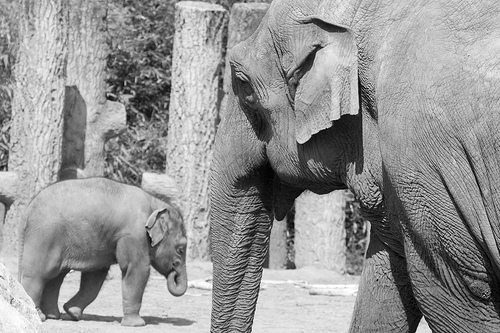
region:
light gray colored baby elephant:
[12, 175, 190, 331]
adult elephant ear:
[276, 12, 366, 148]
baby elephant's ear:
[142, 206, 175, 251]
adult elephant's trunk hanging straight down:
[198, 103, 278, 330]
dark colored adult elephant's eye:
[227, 65, 260, 105]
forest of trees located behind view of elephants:
[2, 0, 382, 277]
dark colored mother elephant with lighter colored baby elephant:
[12, 23, 494, 330]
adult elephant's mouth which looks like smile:
[247, 140, 318, 227]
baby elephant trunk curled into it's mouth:
[159, 260, 198, 301]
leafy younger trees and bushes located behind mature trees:
[1, 0, 364, 273]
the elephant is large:
[206, 4, 498, 331]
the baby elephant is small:
[17, 173, 191, 330]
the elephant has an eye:
[209, 3, 497, 332]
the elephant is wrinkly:
[206, 0, 498, 332]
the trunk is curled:
[161, 273, 193, 296]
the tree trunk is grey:
[4, 5, 218, 175]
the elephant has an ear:
[201, 0, 498, 332]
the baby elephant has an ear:
[16, 179, 193, 327]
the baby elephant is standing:
[12, 176, 195, 313]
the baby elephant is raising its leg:
[22, 175, 194, 321]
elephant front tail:
[192, 192, 289, 329]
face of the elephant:
[166, 13, 356, 245]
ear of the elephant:
[278, 23, 374, 141]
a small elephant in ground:
[21, 165, 209, 321]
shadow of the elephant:
[91, 303, 202, 328]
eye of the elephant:
[221, 55, 281, 113]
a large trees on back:
[8, 0, 273, 330]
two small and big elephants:
[17, 23, 489, 332]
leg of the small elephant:
[106, 273, 158, 329]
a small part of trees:
[104, 0, 179, 131]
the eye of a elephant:
[186, 56, 288, 113]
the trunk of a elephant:
[194, 170, 336, 322]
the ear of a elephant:
[286, 4, 372, 141]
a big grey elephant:
[177, 2, 494, 326]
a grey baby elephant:
[15, 180, 212, 303]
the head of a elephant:
[195, 2, 410, 196]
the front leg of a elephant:
[113, 227, 167, 329]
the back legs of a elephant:
[25, 213, 72, 325]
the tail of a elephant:
[11, 209, 45, 270]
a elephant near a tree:
[20, 125, 224, 295]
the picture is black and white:
[11, 5, 482, 319]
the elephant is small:
[0, 161, 210, 307]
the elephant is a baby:
[5, 160, 200, 306]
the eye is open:
[198, 55, 274, 119]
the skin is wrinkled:
[278, 109, 482, 322]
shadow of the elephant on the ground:
[38, 292, 199, 329]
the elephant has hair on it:
[47, 167, 192, 242]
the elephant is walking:
[20, 169, 197, 315]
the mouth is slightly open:
[246, 178, 296, 229]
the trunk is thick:
[197, 155, 282, 316]